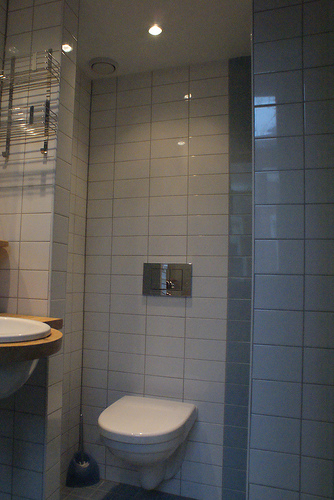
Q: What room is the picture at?
A: It is at the bathroom.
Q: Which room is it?
A: It is a bathroom.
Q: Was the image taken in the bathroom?
A: Yes, it was taken in the bathroom.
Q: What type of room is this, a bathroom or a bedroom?
A: It is a bathroom.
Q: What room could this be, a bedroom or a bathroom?
A: It is a bathroom.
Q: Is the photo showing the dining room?
A: No, the picture is showing the bathroom.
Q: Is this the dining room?
A: No, it is the bathroom.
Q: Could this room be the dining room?
A: No, it is the bathroom.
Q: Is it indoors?
A: Yes, it is indoors.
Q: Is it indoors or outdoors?
A: It is indoors.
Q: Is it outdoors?
A: No, it is indoors.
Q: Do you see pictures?
A: No, there are no pictures.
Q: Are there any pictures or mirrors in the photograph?
A: No, there are no pictures or mirrors.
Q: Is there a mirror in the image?
A: No, there are no mirrors.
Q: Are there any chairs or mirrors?
A: No, there are no mirrors or chairs.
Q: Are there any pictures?
A: No, there are no pictures.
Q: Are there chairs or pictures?
A: No, there are no pictures or chairs.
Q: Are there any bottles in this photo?
A: No, there are no bottles.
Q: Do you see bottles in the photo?
A: No, there are no bottles.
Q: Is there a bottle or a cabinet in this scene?
A: No, there are no bottles or cabinets.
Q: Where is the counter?
A: The counter is in the bathroom.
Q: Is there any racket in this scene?
A: No, there are no rackets.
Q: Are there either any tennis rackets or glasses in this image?
A: No, there are no tennis rackets or glasses.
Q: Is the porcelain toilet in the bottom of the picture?
A: Yes, the toilet is in the bottom of the image.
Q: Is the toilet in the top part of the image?
A: No, the toilet is in the bottom of the image.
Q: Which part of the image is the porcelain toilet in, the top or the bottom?
A: The toilet is in the bottom of the image.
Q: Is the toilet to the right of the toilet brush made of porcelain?
A: Yes, the toilet is made of porcelain.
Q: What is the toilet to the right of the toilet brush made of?
A: The toilet is made of porcelain.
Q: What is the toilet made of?
A: The toilet is made of porcelain.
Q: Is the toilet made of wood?
A: No, the toilet is made of porcelain.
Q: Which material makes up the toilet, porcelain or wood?
A: The toilet is made of porcelain.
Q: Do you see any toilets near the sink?
A: Yes, there is a toilet near the sink.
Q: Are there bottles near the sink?
A: No, there is a toilet near the sink.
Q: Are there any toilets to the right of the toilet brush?
A: Yes, there is a toilet to the right of the toilet brush.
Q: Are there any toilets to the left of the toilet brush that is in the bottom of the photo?
A: No, the toilet is to the right of the toilet brush.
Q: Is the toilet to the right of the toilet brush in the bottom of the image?
A: Yes, the toilet is to the right of the toilet brush.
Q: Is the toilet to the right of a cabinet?
A: No, the toilet is to the right of the toilet brush.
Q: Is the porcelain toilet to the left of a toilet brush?
A: No, the toilet is to the right of a toilet brush.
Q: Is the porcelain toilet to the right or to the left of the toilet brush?
A: The toilet is to the right of the toilet brush.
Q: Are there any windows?
A: Yes, there is a window.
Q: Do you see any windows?
A: Yes, there is a window.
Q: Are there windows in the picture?
A: Yes, there is a window.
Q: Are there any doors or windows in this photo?
A: Yes, there is a window.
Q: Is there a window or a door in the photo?
A: Yes, there is a window.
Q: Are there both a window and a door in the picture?
A: No, there is a window but no doors.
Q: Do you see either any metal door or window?
A: Yes, there is a metal window.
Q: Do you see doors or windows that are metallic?
A: Yes, the window is metallic.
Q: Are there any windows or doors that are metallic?
A: Yes, the window is metallic.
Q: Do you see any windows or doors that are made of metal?
A: Yes, the window is made of metal.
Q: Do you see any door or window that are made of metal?
A: Yes, the window is made of metal.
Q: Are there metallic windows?
A: Yes, there is a metal window.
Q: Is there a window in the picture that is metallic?
A: Yes, there is a window that is metallic.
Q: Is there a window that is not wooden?
A: Yes, there is a metallic window.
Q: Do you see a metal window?
A: Yes, there is a window that is made of metal.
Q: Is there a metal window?
A: Yes, there is a window that is made of metal.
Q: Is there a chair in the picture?
A: No, there are no chairs.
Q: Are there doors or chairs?
A: No, there are no chairs or doors.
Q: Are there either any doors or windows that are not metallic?
A: No, there is a window but it is metallic.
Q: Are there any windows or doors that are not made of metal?
A: No, there is a window but it is made of metal.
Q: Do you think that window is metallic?
A: Yes, the window is metallic.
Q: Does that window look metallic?
A: Yes, the window is metallic.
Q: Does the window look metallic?
A: Yes, the window is metallic.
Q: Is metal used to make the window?
A: Yes, the window is made of metal.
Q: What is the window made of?
A: The window is made of metal.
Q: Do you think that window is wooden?
A: No, the window is metallic.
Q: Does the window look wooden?
A: No, the window is metallic.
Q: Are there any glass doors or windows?
A: No, there is a window but it is metallic.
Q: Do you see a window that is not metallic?
A: No, there is a window but it is metallic.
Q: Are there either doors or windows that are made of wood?
A: No, there is a window but it is made of metal.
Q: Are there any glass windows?
A: No, there is a window but it is made of metal.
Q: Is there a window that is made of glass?
A: No, there is a window but it is made of metal.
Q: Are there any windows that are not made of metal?
A: No, there is a window but it is made of metal.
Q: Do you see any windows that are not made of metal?
A: No, there is a window but it is made of metal.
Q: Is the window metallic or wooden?
A: The window is metallic.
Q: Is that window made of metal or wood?
A: The window is made of metal.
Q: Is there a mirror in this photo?
A: No, there are no mirrors.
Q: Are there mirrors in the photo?
A: No, there are no mirrors.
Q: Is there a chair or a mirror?
A: No, there are no mirrors or chairs.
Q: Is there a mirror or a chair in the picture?
A: No, there are no mirrors or chairs.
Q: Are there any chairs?
A: No, there are no chairs.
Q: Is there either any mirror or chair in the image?
A: No, there are no chairs or mirrors.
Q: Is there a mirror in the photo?
A: No, there are no mirrors.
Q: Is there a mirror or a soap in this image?
A: No, there are no mirrors or soaps.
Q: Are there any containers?
A: No, there are no containers.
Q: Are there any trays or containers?
A: No, there are no containers or trays.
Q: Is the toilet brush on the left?
A: Yes, the toilet brush is on the left of the image.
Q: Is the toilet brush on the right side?
A: No, the toilet brush is on the left of the image.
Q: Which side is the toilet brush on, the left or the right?
A: The toilet brush is on the left of the image.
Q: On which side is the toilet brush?
A: The toilet brush is on the left of the image.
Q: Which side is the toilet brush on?
A: The toilet brush is on the left of the image.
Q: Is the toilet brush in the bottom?
A: Yes, the toilet brush is in the bottom of the image.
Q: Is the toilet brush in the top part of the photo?
A: No, the toilet brush is in the bottom of the image.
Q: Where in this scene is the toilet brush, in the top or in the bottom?
A: The toilet brush is in the bottom of the image.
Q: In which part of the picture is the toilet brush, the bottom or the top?
A: The toilet brush is in the bottom of the image.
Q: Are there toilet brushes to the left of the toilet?
A: Yes, there is a toilet brush to the left of the toilet.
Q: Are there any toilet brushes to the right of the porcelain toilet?
A: No, the toilet brush is to the left of the toilet.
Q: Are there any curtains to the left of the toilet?
A: No, there is a toilet brush to the left of the toilet.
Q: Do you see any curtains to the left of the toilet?
A: No, there is a toilet brush to the left of the toilet.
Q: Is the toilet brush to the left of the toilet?
A: Yes, the toilet brush is to the left of the toilet.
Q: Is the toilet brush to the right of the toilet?
A: No, the toilet brush is to the left of the toilet.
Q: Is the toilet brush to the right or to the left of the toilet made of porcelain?
A: The toilet brush is to the left of the toilet.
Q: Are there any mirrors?
A: No, there are no mirrors.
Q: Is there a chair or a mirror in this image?
A: No, there are no mirrors or chairs.